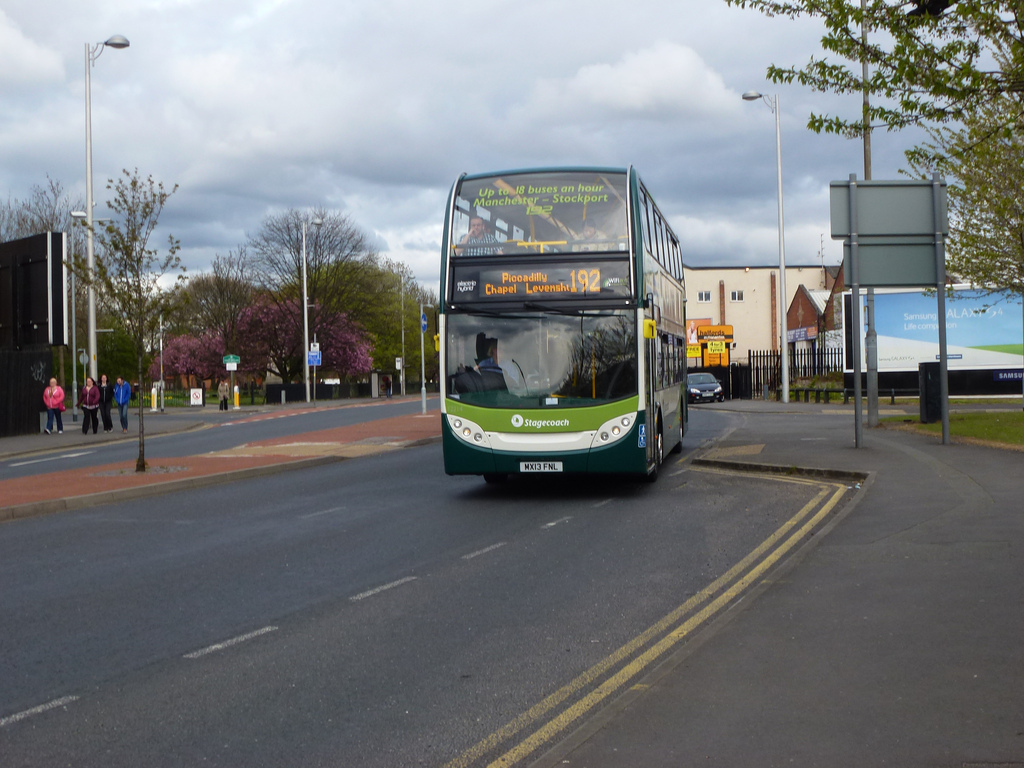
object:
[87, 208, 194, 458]
tree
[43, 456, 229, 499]
divider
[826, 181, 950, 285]
signs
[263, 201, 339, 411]
streetlight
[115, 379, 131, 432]
pedestrian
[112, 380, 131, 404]
jacket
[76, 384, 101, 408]
jacket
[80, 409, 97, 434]
pants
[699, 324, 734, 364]
signage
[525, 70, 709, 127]
cloud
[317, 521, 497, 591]
marking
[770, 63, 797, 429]
pole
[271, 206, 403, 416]
tree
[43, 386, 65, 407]
jacket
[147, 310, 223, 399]
tree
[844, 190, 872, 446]
poles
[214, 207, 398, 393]
tree branches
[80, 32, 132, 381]
street light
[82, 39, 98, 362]
pole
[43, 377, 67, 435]
people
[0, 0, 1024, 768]
outdoors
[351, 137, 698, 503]
lines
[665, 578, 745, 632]
lines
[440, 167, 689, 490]
bus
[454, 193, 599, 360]
glass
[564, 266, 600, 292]
group